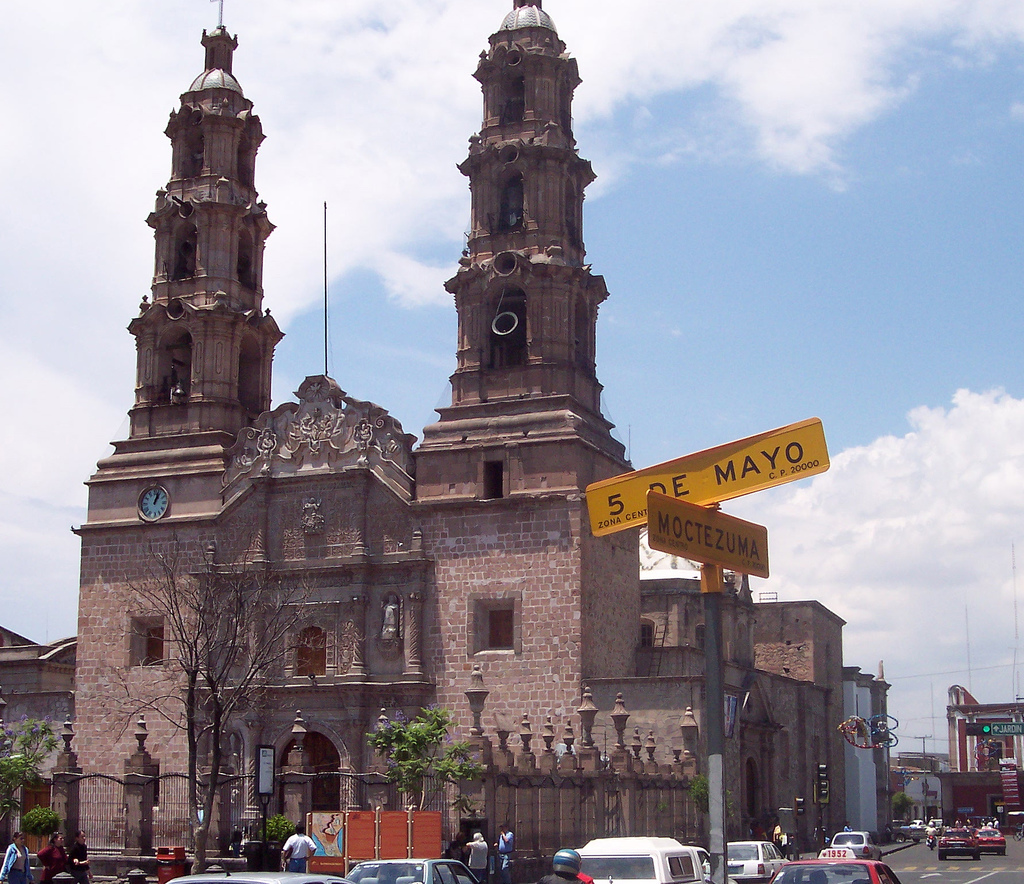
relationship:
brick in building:
[90, 659, 113, 670] [67, 5, 842, 847]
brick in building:
[146, 721, 166, 729] [67, 5, 842, 847]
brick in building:
[140, 548, 153, 571] [67, 5, 842, 847]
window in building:
[469, 588, 515, 658] [67, 5, 842, 847]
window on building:
[484, 463, 503, 501] [67, 5, 842, 847]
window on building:
[298, 621, 322, 669] [67, 5, 842, 847]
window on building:
[131, 618, 161, 666] [67, 5, 842, 847]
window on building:
[488, 288, 528, 365] [67, 5, 842, 847]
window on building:
[495, 174, 525, 235] [67, 5, 842, 847]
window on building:
[563, 182, 583, 243] [67, 5, 842, 847]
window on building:
[501, 70, 522, 119] [67, 5, 842, 847]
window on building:
[184, 133, 201, 171] [67, 5, 842, 847]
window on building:
[168, 222, 195, 283] [67, 5, 842, 847]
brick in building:
[487, 689, 513, 705] [67, 5, 842, 847]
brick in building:
[498, 533, 525, 564] [839, 664, 909, 839]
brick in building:
[513, 547, 539, 561] [931, 654, 1021, 825]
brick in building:
[543, 547, 572, 561] [67, 5, 842, 847]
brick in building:
[577, 594, 595, 616] [836, 660, 906, 838]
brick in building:
[521, 689, 547, 703] [918, 667, 1021, 830]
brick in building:
[89, 659, 116, 696] [67, 5, 842, 847]